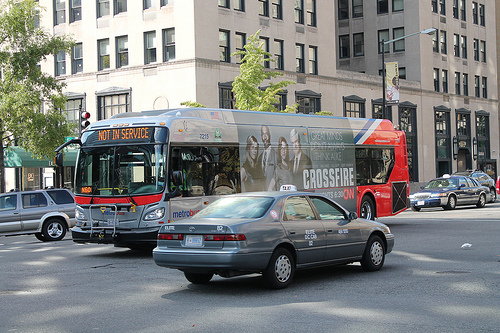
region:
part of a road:
[426, 292, 476, 322]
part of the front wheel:
[358, 233, 386, 272]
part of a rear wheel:
[269, 262, 290, 292]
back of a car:
[178, 220, 230, 278]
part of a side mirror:
[343, 206, 358, 223]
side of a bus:
[241, 121, 315, 163]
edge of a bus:
[393, 143, 416, 177]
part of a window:
[91, 152, 141, 194]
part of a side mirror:
[44, 142, 76, 177]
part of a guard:
[91, 200, 121, 230]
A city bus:
[54, 98, 407, 205]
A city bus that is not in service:
[62, 113, 176, 233]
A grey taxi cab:
[178, 169, 408, 296]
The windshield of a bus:
[69, 141, 171, 204]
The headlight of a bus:
[129, 200, 169, 237]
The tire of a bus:
[353, 187, 393, 223]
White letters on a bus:
[283, 146, 360, 195]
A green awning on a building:
[9, 131, 92, 188]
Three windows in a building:
[207, 20, 330, 81]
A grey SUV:
[7, 164, 83, 267]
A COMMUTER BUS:
[61, 121, 433, 260]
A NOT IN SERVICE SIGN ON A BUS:
[75, 120, 176, 149]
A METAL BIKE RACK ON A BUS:
[79, 201, 136, 246]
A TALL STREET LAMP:
[376, 20, 443, 129]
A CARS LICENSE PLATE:
[171, 229, 224, 256]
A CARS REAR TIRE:
[262, 238, 319, 293]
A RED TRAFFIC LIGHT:
[59, 83, 105, 143]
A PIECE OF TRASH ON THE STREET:
[439, 227, 484, 264]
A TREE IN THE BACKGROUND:
[1, 6, 77, 176]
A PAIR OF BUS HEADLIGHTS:
[72, 196, 170, 226]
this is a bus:
[101, 117, 391, 190]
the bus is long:
[74, 125, 394, 190]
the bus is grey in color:
[247, 133, 349, 179]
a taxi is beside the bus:
[151, 197, 387, 287]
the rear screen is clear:
[77, 149, 162, 189]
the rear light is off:
[140, 205, 161, 223]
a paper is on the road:
[456, 243, 477, 255]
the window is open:
[147, 45, 154, 61]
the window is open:
[316, 204, 331, 217]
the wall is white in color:
[187, 15, 210, 100]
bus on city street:
[60, 113, 412, 257]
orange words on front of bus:
[89, 123, 154, 154]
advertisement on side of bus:
[242, 130, 354, 191]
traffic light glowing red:
[71, 105, 103, 141]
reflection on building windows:
[431, 103, 453, 160]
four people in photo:
[238, 121, 311, 174]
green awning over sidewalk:
[4, 136, 71, 175]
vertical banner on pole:
[378, 47, 405, 117]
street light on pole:
[402, 21, 447, 47]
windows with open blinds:
[94, 31, 131, 76]